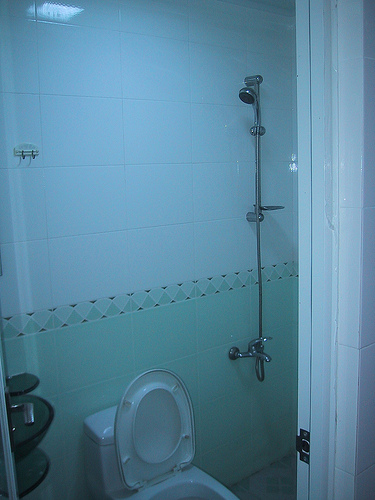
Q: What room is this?
A: It is a bathroom.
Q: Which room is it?
A: It is a bathroom.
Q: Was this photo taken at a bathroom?
A: Yes, it was taken in a bathroom.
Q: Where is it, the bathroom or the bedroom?
A: It is the bathroom.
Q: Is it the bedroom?
A: No, it is the bathroom.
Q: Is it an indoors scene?
A: Yes, it is indoors.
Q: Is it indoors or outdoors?
A: It is indoors.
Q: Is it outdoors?
A: No, it is indoors.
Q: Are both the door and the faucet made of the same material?
A: Yes, both the door and the faucet are made of metal.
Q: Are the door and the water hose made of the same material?
A: Yes, both the door and the water hose are made of metal.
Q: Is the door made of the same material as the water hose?
A: Yes, both the door and the water hose are made of metal.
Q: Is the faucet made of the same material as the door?
A: Yes, both the faucet and the door are made of metal.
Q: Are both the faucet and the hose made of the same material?
A: Yes, both the faucet and the hose are made of metal.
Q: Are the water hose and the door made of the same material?
A: Yes, both the water hose and the door are made of metal.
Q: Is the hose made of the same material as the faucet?
A: Yes, both the hose and the faucet are made of metal.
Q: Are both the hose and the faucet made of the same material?
A: Yes, both the hose and the faucet are made of metal.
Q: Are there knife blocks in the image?
A: No, there are no knife blocks.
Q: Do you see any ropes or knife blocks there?
A: No, there are no knife blocks or ropes.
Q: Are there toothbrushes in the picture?
A: No, there are no toothbrushes.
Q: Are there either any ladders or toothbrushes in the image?
A: No, there are no toothbrushes or ladders.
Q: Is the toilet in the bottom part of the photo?
A: Yes, the toilet is in the bottom of the image.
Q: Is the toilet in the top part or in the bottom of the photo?
A: The toilet is in the bottom of the image.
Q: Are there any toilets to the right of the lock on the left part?
A: Yes, there is a toilet to the right of the lock.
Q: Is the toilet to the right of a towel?
A: No, the toilet is to the right of the lock.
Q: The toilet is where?
A: The toilet is in the bathroom.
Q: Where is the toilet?
A: The toilet is in the bathroom.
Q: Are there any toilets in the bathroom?
A: Yes, there is a toilet in the bathroom.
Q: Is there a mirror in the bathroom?
A: No, there is a toilet in the bathroom.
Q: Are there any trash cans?
A: No, there are no trash cans.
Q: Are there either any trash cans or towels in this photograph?
A: No, there are no trash cans or towels.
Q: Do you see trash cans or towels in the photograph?
A: No, there are no trash cans or towels.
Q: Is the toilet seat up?
A: Yes, the toilet seat is up.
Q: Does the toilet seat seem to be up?
A: Yes, the toilet seat is up.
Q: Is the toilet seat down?
A: No, the toilet seat is up.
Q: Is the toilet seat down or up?
A: The toilet seat is up.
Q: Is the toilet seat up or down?
A: The toilet seat is up.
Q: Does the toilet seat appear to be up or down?
A: The toilet seat is up.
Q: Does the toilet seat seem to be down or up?
A: The toilet seat is up.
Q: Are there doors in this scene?
A: Yes, there is a door.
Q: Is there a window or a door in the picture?
A: Yes, there is a door.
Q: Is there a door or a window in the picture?
A: Yes, there is a door.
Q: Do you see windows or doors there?
A: Yes, there is a door.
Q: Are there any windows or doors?
A: Yes, there is a door.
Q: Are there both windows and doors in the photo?
A: No, there is a door but no windows.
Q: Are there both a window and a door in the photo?
A: No, there is a door but no windows.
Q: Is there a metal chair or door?
A: Yes, there is a metal door.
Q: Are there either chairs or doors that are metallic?
A: Yes, the door is metallic.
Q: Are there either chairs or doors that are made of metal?
A: Yes, the door is made of metal.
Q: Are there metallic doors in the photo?
A: Yes, there is a metal door.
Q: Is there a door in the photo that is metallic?
A: Yes, there is a door that is metallic.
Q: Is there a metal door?
A: Yes, there is a door that is made of metal.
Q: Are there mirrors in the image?
A: No, there are no mirrors.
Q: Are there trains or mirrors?
A: No, there are no mirrors or trains.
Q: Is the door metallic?
A: Yes, the door is metallic.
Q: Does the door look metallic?
A: Yes, the door is metallic.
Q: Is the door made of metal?
A: Yes, the door is made of metal.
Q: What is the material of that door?
A: The door is made of metal.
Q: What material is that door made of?
A: The door is made of metal.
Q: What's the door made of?
A: The door is made of metal.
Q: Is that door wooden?
A: No, the door is metallic.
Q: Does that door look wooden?
A: No, the door is metallic.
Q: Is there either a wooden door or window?
A: No, there is a door but it is metallic.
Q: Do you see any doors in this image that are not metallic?
A: No, there is a door but it is metallic.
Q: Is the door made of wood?
A: No, the door is made of metal.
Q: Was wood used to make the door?
A: No, the door is made of metal.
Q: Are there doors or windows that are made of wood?
A: No, there is a door but it is made of metal.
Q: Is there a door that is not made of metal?
A: No, there is a door but it is made of metal.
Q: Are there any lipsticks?
A: No, there are no lipsticks.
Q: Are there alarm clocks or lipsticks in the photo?
A: No, there are no lipsticks or alarm clocks.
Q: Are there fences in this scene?
A: No, there are no fences.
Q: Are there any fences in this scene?
A: No, there are no fences.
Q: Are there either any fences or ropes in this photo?
A: No, there are no fences or ropes.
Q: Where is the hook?
A: The hook is in the bathroom.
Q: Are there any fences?
A: No, there are no fences.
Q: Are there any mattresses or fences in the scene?
A: No, there are no fences or mattresses.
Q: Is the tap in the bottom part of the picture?
A: Yes, the tap is in the bottom of the image.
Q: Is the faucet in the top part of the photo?
A: No, the faucet is in the bottom of the image.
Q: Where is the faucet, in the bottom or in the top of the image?
A: The faucet is in the bottom of the image.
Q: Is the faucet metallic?
A: Yes, the faucet is metallic.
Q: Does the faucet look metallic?
A: Yes, the faucet is metallic.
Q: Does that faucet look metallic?
A: Yes, the faucet is metallic.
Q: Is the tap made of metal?
A: Yes, the tap is made of metal.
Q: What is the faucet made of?
A: The faucet is made of metal.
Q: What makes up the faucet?
A: The faucet is made of metal.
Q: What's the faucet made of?
A: The faucet is made of metal.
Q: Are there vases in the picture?
A: No, there are no vases.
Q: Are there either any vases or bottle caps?
A: No, there are no vases or bottle caps.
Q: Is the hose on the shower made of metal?
A: Yes, the water hose is made of metal.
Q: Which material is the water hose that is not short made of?
A: The water hose is made of metal.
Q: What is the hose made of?
A: The water hose is made of metal.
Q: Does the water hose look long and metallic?
A: Yes, the water hose is long and metallic.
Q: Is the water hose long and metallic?
A: Yes, the water hose is long and metallic.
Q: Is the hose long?
A: Yes, the hose is long.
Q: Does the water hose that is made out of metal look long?
A: Yes, the water hose is long.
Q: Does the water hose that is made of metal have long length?
A: Yes, the water hose is long.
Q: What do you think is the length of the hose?
A: The hose is long.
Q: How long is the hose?
A: The hose is long.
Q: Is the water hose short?
A: No, the water hose is long.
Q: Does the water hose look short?
A: No, the water hose is long.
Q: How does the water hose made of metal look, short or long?
A: The water hose is long.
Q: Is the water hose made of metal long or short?
A: The water hose is long.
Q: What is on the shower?
A: The water hose is on the shower.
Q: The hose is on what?
A: The hose is on the shower.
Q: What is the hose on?
A: The hose is on the shower.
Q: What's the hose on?
A: The hose is on the shower.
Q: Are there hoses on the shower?
A: Yes, there is a hose on the shower.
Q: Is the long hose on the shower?
A: Yes, the water hose is on the shower.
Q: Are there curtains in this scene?
A: No, there are no curtains.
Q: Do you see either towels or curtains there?
A: No, there are no curtains or towels.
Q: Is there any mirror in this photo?
A: No, there are no mirrors.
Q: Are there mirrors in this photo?
A: No, there are no mirrors.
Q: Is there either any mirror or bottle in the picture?
A: No, there are no mirrors or bottles.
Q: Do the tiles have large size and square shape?
A: Yes, the tiles are large and square.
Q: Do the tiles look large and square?
A: Yes, the tiles are large and square.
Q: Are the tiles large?
A: Yes, the tiles are large.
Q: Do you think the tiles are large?
A: Yes, the tiles are large.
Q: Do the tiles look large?
A: Yes, the tiles are large.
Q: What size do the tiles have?
A: The tiles have large size.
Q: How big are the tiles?
A: The tiles are large.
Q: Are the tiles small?
A: No, the tiles are large.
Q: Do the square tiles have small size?
A: No, the tiles are large.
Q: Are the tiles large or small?
A: The tiles are large.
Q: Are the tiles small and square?
A: No, the tiles are square but large.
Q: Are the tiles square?
A: Yes, the tiles are square.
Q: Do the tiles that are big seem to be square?
A: Yes, the tiles are square.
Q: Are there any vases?
A: No, there are no vases.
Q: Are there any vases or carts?
A: No, there are no vases or carts.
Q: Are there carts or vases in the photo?
A: No, there are no vases or carts.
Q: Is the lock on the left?
A: Yes, the lock is on the left of the image.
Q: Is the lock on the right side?
A: No, the lock is on the left of the image.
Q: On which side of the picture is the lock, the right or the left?
A: The lock is on the left of the image.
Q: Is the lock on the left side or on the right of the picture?
A: The lock is on the left of the image.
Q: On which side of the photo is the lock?
A: The lock is on the left of the image.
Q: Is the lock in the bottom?
A: Yes, the lock is in the bottom of the image.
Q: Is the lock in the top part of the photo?
A: No, the lock is in the bottom of the image.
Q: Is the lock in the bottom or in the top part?
A: The lock is in the bottom of the image.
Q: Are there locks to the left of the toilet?
A: Yes, there is a lock to the left of the toilet.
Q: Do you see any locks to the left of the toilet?
A: Yes, there is a lock to the left of the toilet.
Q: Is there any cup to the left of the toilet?
A: No, there is a lock to the left of the toilet.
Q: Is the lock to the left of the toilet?
A: Yes, the lock is to the left of the toilet.